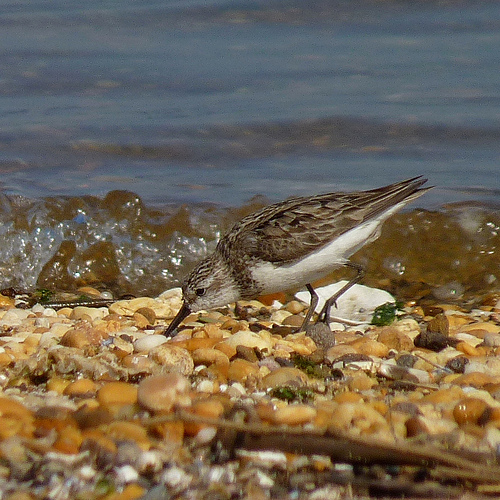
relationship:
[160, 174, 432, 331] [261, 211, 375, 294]
bird has underbelly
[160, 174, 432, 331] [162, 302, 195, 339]
bird has beak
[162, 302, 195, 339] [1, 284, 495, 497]
beak under pebbles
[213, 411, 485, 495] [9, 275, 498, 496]
twigs on ground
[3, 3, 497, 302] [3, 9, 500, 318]
water in background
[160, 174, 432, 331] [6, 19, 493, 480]
bird on beach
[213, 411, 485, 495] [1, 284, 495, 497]
twigs on pebbles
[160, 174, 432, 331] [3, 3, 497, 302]
bird near ocean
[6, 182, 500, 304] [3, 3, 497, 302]
wave of water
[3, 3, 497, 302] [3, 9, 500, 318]
ocean in background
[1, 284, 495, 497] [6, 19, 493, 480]
pebbles on shore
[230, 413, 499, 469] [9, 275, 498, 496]
stick on ground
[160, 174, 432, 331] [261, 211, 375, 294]
bird has chest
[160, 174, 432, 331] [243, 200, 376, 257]
bird has wing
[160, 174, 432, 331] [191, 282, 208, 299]
bird has eye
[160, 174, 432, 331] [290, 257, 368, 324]
bird has feet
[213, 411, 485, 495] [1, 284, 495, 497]
sticks on pebbles